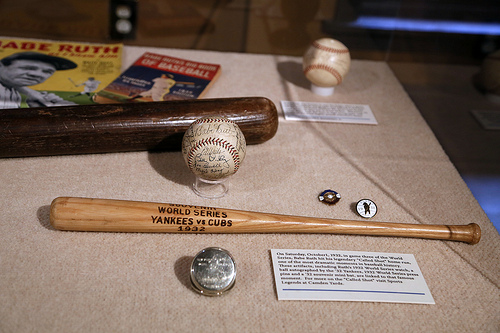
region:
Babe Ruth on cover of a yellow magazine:
[0, 36, 125, 108]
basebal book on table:
[92, 51, 222, 103]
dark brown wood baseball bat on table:
[0, 97, 277, 157]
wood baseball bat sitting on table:
[48, 195, 480, 243]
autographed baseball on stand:
[181, 114, 248, 198]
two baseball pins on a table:
[316, 187, 377, 217]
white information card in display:
[278, 99, 378, 125]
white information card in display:
[271, 249, 436, 306]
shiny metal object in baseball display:
[191, 246, 235, 294]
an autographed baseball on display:
[300, 36, 351, 95]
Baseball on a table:
[179, 113, 249, 180]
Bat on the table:
[48, 185, 481, 246]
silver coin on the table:
[177, 241, 242, 300]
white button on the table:
[352, 200, 377, 214]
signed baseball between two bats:
[175, 109, 242, 182]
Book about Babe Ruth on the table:
[0, 24, 128, 107]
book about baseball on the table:
[90, 34, 217, 115]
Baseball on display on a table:
[301, 32, 346, 88]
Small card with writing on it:
[263, 240, 443, 310]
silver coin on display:
[186, 248, 243, 295]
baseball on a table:
[160, 111, 255, 191]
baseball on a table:
[283, 25, 378, 115]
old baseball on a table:
[152, 119, 293, 203]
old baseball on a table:
[272, 23, 363, 107]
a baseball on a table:
[172, 111, 263, 198]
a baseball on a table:
[275, 22, 366, 107]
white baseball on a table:
[160, 108, 274, 202]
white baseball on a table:
[303, 38, 355, 99]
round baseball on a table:
[156, 108, 270, 200]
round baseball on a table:
[280, 36, 380, 110]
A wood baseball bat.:
[51, 193, 481, 245]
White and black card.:
[268, 250, 433, 303]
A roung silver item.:
[185, 245, 238, 295]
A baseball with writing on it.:
[180, 113, 247, 181]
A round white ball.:
[301, 36, 351, 85]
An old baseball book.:
[93, 48, 223, 109]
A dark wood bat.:
[0, 95, 279, 157]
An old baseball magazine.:
[0, 35, 124, 107]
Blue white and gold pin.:
[317, 188, 342, 207]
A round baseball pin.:
[355, 195, 378, 219]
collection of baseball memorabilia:
[3, 36, 494, 330]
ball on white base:
[303, 37, 348, 97]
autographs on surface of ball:
[183, 115, 246, 178]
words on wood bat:
[50, 197, 484, 242]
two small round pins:
[318, 189, 376, 218]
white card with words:
[269, 247, 435, 304]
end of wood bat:
[1, 97, 277, 159]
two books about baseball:
[2, 33, 218, 109]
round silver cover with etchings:
[188, 246, 236, 296]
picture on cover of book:
[1, 52, 77, 106]